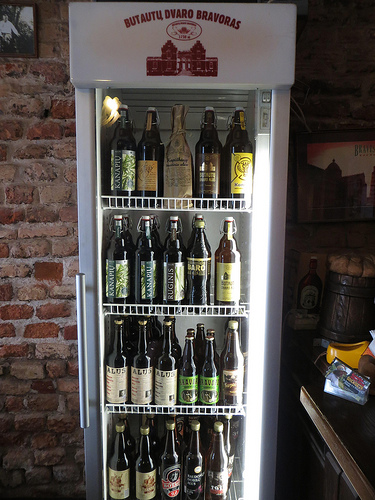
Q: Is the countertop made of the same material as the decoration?
A: Yes, both the countertop and the decoration are made of wood.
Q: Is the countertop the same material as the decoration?
A: Yes, both the countertop and the decoration are made of wood.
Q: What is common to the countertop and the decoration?
A: The material, both the countertop and the decoration are wooden.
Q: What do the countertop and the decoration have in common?
A: The material, both the countertop and the decoration are wooden.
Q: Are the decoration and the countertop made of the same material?
A: Yes, both the decoration and the countertop are made of wood.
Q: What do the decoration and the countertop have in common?
A: The material, both the decoration and the countertop are wooden.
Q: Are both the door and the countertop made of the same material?
A: No, the door is made of glass and the countertop is made of wood.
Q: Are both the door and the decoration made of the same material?
A: No, the door is made of glass and the decoration is made of wood.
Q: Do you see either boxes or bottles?
A: Yes, there is a bottle.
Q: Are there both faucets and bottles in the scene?
A: No, there is a bottle but no faucets.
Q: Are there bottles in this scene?
A: Yes, there is a bottle.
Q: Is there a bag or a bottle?
A: Yes, there is a bottle.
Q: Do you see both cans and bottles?
A: No, there is a bottle but no cans.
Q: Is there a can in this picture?
A: No, there are no cans.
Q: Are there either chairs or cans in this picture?
A: No, there are no cans or chairs.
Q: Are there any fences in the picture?
A: No, there are no fences.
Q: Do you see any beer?
A: Yes, there is beer.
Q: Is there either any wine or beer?
A: Yes, there is beer.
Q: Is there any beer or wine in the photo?
A: Yes, there is beer.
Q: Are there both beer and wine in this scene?
A: No, there is beer but no wine.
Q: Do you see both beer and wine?
A: No, there is beer but no wine.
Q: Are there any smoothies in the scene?
A: No, there are no smoothies.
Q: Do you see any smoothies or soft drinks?
A: No, there are no smoothies or soft drinks.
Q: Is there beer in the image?
A: Yes, there is beer.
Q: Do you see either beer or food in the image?
A: Yes, there is beer.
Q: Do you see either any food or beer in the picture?
A: Yes, there is beer.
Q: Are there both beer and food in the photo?
A: No, there is beer but no food.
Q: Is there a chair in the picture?
A: No, there are no chairs.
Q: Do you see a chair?
A: No, there are no chairs.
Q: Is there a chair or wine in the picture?
A: No, there are no chairs or wine.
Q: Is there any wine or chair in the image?
A: No, there are no chairs or wine.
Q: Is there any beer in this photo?
A: Yes, there is beer.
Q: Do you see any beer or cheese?
A: Yes, there is beer.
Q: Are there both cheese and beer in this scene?
A: No, there is beer but no cheese.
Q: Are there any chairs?
A: No, there are no chairs.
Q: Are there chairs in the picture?
A: No, there are no chairs.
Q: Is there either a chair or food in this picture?
A: No, there are no chairs or food.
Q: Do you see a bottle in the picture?
A: Yes, there is a bottle.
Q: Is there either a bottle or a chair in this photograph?
A: Yes, there is a bottle.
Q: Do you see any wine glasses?
A: No, there are no wine glasses.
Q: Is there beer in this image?
A: Yes, there is beer.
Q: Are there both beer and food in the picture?
A: No, there is beer but no food.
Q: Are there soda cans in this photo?
A: No, there are no soda cans.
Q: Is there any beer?
A: Yes, there is beer.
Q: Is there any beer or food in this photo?
A: Yes, there is beer.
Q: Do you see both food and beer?
A: No, there is beer but no food.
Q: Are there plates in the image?
A: No, there are no plates.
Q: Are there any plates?
A: No, there are no plates.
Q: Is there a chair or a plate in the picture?
A: No, there are no plates or chairs.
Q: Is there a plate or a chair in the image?
A: No, there are no plates or chairs.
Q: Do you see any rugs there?
A: No, there are no rugs.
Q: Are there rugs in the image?
A: No, there are no rugs.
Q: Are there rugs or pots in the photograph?
A: No, there are no rugs or pots.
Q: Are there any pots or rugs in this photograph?
A: No, there are no rugs or pots.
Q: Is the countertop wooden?
A: Yes, the countertop is wooden.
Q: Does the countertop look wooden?
A: Yes, the countertop is wooden.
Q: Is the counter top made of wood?
A: Yes, the counter top is made of wood.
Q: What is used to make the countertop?
A: The countertop is made of wood.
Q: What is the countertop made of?
A: The countertop is made of wood.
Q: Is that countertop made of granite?
A: No, the countertop is made of wood.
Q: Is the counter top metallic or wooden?
A: The counter top is wooden.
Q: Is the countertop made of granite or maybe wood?
A: The countertop is made of wood.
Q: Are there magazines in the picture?
A: No, there are no magazines.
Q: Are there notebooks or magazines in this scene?
A: No, there are no magazines or notebooks.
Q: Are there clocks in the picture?
A: No, there are no clocks.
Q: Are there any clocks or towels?
A: No, there are no clocks or towels.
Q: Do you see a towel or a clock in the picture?
A: No, there are no clocks or towels.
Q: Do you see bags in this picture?
A: No, there are no bags.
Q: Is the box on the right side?
A: Yes, the box is on the right of the image.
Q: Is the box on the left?
A: No, the box is on the right of the image.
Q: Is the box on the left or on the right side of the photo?
A: The box is on the right of the image.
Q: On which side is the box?
A: The box is on the right of the image.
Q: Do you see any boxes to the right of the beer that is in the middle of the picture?
A: Yes, there is a box to the right of the beer.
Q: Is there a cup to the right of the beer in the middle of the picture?
A: No, there is a box to the right of the beer.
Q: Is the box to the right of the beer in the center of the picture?
A: Yes, the box is to the right of the beer.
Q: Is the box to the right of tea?
A: No, the box is to the right of the beer.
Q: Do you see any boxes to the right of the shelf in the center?
A: Yes, there is a box to the right of the shelf.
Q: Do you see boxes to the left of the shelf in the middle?
A: No, the box is to the right of the shelf.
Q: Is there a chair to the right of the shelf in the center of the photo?
A: No, there is a box to the right of the shelf.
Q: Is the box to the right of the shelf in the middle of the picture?
A: Yes, the box is to the right of the shelf.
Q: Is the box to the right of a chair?
A: No, the box is to the right of the shelf.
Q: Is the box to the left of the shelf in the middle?
A: No, the box is to the right of the shelf.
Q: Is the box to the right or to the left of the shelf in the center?
A: The box is to the right of the shelf.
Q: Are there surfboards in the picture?
A: No, there are no surfboards.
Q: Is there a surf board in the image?
A: No, there are no surfboards.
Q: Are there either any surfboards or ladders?
A: No, there are no surfboards or ladders.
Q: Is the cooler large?
A: Yes, the cooler is large.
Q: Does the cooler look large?
A: Yes, the cooler is large.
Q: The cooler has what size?
A: The cooler is large.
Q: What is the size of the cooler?
A: The cooler is large.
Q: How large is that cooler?
A: The cooler is large.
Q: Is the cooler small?
A: No, the cooler is large.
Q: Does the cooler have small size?
A: No, the cooler is large.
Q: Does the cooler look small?
A: No, the cooler is large.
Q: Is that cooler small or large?
A: The cooler is large.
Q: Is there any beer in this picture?
A: Yes, there is beer.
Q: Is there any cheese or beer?
A: Yes, there is beer.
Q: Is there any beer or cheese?
A: Yes, there is beer.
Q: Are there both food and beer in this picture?
A: No, there is beer but no food.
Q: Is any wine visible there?
A: No, there is no wine.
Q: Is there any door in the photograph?
A: Yes, there is a door.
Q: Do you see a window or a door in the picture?
A: Yes, there is a door.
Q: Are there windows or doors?
A: Yes, there is a door.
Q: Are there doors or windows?
A: Yes, there is a door.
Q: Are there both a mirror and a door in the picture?
A: No, there is a door but no mirrors.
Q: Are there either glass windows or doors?
A: Yes, there is a glass door.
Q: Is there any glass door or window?
A: Yes, there is a glass door.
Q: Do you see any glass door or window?
A: Yes, there is a glass door.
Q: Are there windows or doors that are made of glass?
A: Yes, the door is made of glass.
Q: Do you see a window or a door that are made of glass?
A: Yes, the door is made of glass.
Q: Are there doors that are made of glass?
A: Yes, there is a door that is made of glass.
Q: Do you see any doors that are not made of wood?
A: Yes, there is a door that is made of glass.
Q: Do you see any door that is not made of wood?
A: Yes, there is a door that is made of glass.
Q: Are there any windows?
A: No, there are no windows.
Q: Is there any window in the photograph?
A: No, there are no windows.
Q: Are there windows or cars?
A: No, there are no windows or cars.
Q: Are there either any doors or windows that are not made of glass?
A: No, there is a door but it is made of glass.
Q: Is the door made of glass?
A: Yes, the door is made of glass.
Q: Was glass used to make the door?
A: Yes, the door is made of glass.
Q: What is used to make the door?
A: The door is made of glass.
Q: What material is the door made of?
A: The door is made of glass.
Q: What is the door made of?
A: The door is made of glass.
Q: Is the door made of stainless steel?
A: No, the door is made of glass.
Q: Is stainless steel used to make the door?
A: No, the door is made of glass.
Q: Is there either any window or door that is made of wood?
A: No, there is a door but it is made of glass.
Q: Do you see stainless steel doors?
A: No, there is a door but it is made of glass.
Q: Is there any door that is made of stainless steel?
A: No, there is a door but it is made of glass.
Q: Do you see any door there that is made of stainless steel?
A: No, there is a door but it is made of glass.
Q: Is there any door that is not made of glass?
A: No, there is a door but it is made of glass.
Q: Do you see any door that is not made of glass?
A: No, there is a door but it is made of glass.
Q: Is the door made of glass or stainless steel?
A: The door is made of glass.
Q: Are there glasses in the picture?
A: No, there are no glasses.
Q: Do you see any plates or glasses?
A: No, there are no glasses or plates.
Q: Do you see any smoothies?
A: No, there are no smoothies.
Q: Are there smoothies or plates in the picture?
A: No, there are no smoothies or plates.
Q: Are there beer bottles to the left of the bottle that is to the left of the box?
A: Yes, there is a beer bottle to the left of the bottle.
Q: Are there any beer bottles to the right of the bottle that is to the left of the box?
A: No, the beer bottle is to the left of the bottle.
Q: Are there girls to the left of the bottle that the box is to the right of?
A: No, there is a beer bottle to the left of the bottle.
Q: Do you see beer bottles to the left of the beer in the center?
A: Yes, there is a beer bottle to the left of the beer.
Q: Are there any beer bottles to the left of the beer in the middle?
A: Yes, there is a beer bottle to the left of the beer.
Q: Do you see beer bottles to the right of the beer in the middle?
A: No, the beer bottle is to the left of the beer.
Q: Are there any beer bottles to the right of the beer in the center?
A: No, the beer bottle is to the left of the beer.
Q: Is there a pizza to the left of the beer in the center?
A: No, there is a beer bottle to the left of the beer.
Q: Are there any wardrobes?
A: No, there are no wardrobes.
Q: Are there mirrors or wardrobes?
A: No, there are no wardrobes or mirrors.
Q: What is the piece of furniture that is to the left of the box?
A: The piece of furniture is a shelf.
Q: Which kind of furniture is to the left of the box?
A: The piece of furniture is a shelf.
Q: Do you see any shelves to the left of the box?
A: Yes, there is a shelf to the left of the box.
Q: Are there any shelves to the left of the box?
A: Yes, there is a shelf to the left of the box.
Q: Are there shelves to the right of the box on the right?
A: No, the shelf is to the left of the box.